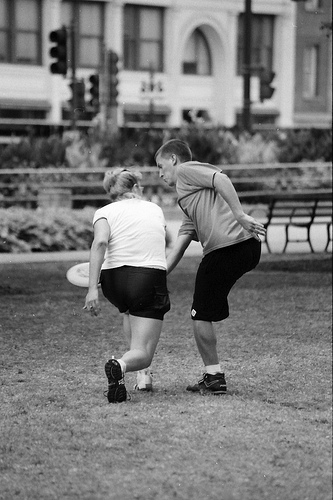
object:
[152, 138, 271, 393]
man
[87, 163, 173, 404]
woman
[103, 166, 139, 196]
hair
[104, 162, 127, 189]
ponytail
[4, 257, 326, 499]
field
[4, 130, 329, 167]
bushes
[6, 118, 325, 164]
roadway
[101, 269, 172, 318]
short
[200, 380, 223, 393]
nike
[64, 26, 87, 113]
stoplights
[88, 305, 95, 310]
ring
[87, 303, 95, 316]
finger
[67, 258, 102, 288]
frisbee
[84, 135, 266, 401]
people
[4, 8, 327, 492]
picture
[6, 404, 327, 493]
grass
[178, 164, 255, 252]
t-shirt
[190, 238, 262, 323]
black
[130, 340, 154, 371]
knee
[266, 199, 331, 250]
sidewalk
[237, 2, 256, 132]
poles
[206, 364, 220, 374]
socks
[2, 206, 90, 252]
bushes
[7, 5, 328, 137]
buildings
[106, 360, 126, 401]
sole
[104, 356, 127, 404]
sneaker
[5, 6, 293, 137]
building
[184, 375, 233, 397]
shoe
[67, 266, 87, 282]
white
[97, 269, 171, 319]
pair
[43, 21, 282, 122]
focus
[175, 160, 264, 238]
grey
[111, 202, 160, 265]
white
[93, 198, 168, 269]
shirt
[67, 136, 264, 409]
playing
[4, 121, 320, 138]
street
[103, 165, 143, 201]
blonde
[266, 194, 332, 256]
bench